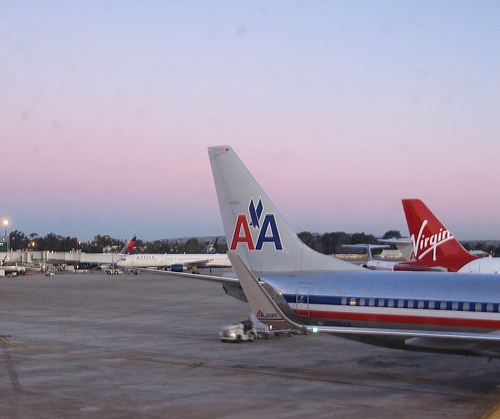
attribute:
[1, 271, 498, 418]
ground — grey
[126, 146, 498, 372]
plane — parked, silver, red, blue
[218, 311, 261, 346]
tram — white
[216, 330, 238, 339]
headlights — on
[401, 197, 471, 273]
tail — red, white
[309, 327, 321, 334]
light — green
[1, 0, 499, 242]
sky — pinkish purple, hazy, blue, pink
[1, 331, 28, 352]
marking — yellow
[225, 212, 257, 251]
letter — red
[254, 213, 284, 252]
letter — blue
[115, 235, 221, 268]
plane — white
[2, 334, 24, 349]
line — yellow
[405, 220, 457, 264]
word — white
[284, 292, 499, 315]
stripe — blue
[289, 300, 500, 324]
line — white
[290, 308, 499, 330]
line — red